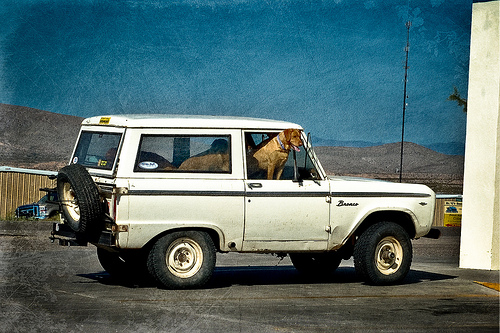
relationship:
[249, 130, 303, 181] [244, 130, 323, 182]
dog at window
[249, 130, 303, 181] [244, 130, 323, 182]
dog at passenger window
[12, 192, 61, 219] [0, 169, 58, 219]
truck parked beside fence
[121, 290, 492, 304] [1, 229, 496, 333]
line on pavement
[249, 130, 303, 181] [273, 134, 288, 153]
dog with collar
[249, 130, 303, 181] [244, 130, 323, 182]
dog hanging out of window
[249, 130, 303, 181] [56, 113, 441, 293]
dog sitting in car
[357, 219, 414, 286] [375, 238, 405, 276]
tire with hubcaps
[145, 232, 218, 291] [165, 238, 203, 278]
tire with hubcaps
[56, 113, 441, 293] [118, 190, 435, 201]
jeep has stripe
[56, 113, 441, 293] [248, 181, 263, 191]
jeep has door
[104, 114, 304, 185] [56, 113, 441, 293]
dogs in jeep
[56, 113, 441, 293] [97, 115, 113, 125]
jeep has sticker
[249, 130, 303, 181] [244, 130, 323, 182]
dog in window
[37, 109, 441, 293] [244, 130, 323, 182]
jeep has window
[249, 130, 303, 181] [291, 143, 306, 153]
dog has mouth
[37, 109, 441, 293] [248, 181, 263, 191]
jeep has a door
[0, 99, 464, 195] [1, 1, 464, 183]
hills on horizon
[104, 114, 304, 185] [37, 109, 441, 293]
dogs inside jeep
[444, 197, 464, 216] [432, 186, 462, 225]
sign on building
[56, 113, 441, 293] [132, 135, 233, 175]
car has window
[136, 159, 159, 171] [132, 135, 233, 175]
sticker on window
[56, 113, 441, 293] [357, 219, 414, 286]
vehicle has a tire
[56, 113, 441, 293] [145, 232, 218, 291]
vehicle has a tire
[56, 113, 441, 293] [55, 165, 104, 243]
vehicle has a tire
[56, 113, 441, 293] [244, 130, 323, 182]
vehicle has a window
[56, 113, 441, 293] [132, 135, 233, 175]
vehicle has a window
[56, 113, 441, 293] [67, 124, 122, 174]
vehicle has a window